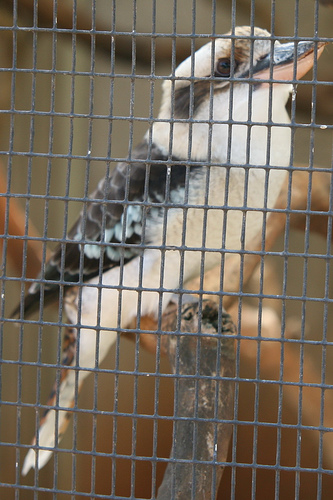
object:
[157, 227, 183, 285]
feathers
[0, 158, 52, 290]
branch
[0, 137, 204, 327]
wing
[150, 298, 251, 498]
perch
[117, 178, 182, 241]
feathers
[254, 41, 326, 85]
beak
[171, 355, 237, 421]
part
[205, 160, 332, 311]
branch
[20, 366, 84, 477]
tail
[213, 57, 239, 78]
brown eyes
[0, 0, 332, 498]
cage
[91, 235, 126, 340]
feathers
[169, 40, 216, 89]
crown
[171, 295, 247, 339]
knot area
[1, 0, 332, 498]
wooden perch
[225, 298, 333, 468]
branch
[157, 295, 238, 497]
branch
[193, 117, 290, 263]
belly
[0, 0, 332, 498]
background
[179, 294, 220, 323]
claws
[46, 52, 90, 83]
wire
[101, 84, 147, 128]
wire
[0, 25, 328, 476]
bird